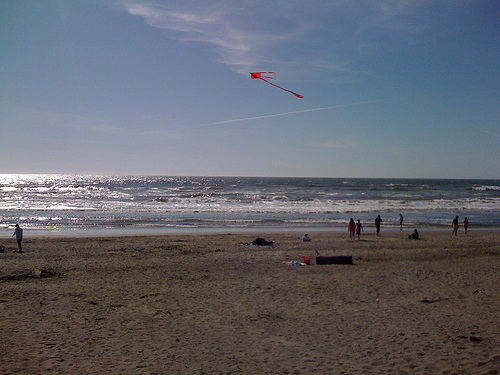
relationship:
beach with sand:
[3, 4, 493, 375] [3, 236, 497, 373]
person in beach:
[11, 224, 22, 253] [3, 4, 493, 375]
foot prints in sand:
[30, 290, 472, 366] [3, 236, 497, 373]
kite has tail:
[249, 66, 307, 102] [266, 72, 307, 102]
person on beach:
[13, 222, 24, 248] [2, 228, 498, 373]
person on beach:
[349, 215, 357, 241] [2, 228, 498, 373]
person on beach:
[354, 219, 363, 240] [2, 228, 498, 373]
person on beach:
[375, 214, 382, 236] [2, 228, 498, 373]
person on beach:
[449, 211, 459, 239] [2, 228, 498, 373]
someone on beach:
[284, 256, 309, 268] [3, 4, 493, 375]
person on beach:
[348, 218, 357, 241] [2, 228, 498, 373]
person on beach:
[355, 215, 365, 241] [2, 228, 498, 373]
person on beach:
[451, 215, 459, 235] [2, 228, 498, 373]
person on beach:
[399, 214, 404, 231] [2, 228, 498, 373]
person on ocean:
[348, 218, 357, 241] [0, 174, 498, 230]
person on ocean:
[354, 219, 363, 240] [0, 174, 498, 230]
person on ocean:
[372, 212, 384, 233] [0, 174, 498, 230]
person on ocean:
[396, 213, 406, 229] [0, 174, 498, 230]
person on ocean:
[451, 215, 459, 235] [0, 174, 498, 230]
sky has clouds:
[3, 5, 499, 177] [120, 5, 430, 84]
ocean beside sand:
[2, 172, 498, 235] [3, 236, 497, 373]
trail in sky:
[206, 100, 345, 132] [3, 5, 499, 177]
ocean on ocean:
[0, 173, 500, 237] [0, 173, 500, 237]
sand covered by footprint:
[3, 236, 497, 373] [89, 293, 99, 310]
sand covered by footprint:
[3, 236, 497, 373] [94, 314, 111, 324]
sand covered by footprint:
[3, 236, 497, 373] [109, 301, 125, 310]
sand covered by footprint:
[3, 236, 497, 373] [144, 290, 162, 300]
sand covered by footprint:
[3, 236, 497, 373] [417, 291, 439, 306]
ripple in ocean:
[86, 214, 112, 223] [0, 174, 498, 230]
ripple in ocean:
[37, 182, 380, 216] [0, 169, 498, 222]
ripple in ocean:
[179, 214, 203, 221] [0, 174, 498, 230]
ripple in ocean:
[37, 182, 380, 216] [0, 174, 498, 230]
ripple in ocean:
[37, 182, 380, 216] [0, 175, 470, 225]